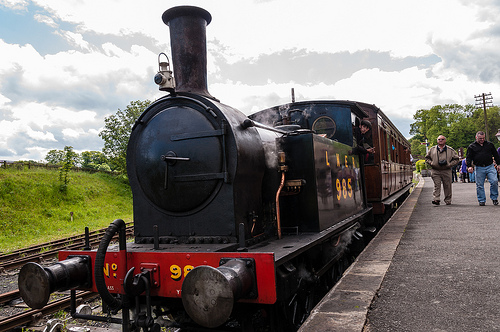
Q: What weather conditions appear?
A: It is cloudy.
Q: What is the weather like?
A: It is cloudy.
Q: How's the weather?
A: It is cloudy.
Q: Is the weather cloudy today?
A: Yes, it is cloudy.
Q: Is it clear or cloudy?
A: It is cloudy.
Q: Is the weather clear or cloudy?
A: It is cloudy.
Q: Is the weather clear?
A: No, it is cloudy.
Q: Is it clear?
A: No, it is cloudy.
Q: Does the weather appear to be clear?
A: No, it is cloudy.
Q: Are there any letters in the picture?
A: Yes, there are letters.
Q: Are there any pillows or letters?
A: Yes, there are letters.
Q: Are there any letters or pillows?
A: Yes, there are letters.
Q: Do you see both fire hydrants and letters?
A: No, there are letters but no fire hydrants.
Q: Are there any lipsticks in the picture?
A: No, there are no lipsticks.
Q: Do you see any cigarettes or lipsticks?
A: No, there are no lipsticks or cigarettes.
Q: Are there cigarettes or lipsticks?
A: No, there are no lipsticks or cigarettes.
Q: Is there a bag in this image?
A: No, there are no bags.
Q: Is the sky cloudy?
A: Yes, the sky is cloudy.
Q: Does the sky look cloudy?
A: Yes, the sky is cloudy.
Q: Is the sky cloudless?
A: No, the sky is cloudy.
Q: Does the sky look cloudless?
A: No, the sky is cloudy.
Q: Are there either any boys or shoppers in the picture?
A: No, there are no boys or shoppers.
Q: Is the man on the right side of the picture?
A: Yes, the man is on the right of the image.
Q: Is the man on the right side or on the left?
A: The man is on the right of the image.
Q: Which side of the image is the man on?
A: The man is on the right of the image.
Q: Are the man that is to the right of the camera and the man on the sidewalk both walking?
A: Yes, both the man and the man are walking.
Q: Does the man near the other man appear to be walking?
A: Yes, the man is walking.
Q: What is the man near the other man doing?
A: The man is walking.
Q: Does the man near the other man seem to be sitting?
A: No, the man is walking.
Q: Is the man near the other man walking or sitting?
A: The man is walking.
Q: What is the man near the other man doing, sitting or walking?
A: The man is walking.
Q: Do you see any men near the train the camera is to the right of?
A: Yes, there is a man near the train.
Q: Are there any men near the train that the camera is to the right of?
A: Yes, there is a man near the train.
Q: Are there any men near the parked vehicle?
A: Yes, there is a man near the train.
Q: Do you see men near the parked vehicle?
A: Yes, there is a man near the train.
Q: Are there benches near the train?
A: No, there is a man near the train.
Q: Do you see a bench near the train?
A: No, there is a man near the train.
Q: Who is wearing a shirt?
A: The man is wearing a shirt.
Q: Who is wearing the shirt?
A: The man is wearing a shirt.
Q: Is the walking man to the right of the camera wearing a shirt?
A: Yes, the man is wearing a shirt.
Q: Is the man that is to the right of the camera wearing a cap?
A: No, the man is wearing a shirt.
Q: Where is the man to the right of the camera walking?
A: The man is walking on the sidewalk.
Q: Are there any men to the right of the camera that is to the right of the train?
A: Yes, there is a man to the right of the camera.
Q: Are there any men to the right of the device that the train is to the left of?
A: Yes, there is a man to the right of the camera.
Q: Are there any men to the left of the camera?
A: No, the man is to the right of the camera.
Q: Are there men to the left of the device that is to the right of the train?
A: No, the man is to the right of the camera.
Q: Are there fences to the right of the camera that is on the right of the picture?
A: No, there is a man to the right of the camera.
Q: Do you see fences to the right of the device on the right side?
A: No, there is a man to the right of the camera.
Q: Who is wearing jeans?
A: The man is wearing jeans.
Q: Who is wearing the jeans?
A: The man is wearing jeans.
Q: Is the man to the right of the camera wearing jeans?
A: Yes, the man is wearing jeans.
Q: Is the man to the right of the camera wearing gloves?
A: No, the man is wearing jeans.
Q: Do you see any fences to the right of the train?
A: No, there is a man to the right of the train.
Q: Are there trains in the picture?
A: Yes, there is a train.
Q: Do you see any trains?
A: Yes, there is a train.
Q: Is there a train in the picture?
A: Yes, there is a train.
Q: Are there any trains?
A: Yes, there is a train.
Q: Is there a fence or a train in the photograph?
A: Yes, there is a train.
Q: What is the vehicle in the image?
A: The vehicle is a train.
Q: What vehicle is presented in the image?
A: The vehicle is a train.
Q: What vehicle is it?
A: The vehicle is a train.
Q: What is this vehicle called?
A: This is a train.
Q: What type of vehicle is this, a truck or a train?
A: This is a train.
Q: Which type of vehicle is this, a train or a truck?
A: This is a train.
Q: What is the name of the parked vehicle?
A: The vehicle is a train.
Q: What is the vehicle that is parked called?
A: The vehicle is a train.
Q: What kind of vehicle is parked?
A: The vehicle is a train.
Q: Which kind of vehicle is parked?
A: The vehicle is a train.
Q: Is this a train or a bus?
A: This is a train.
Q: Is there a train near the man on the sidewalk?
A: Yes, there is a train near the man.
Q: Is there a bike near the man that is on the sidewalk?
A: No, there is a train near the man.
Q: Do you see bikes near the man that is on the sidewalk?
A: No, there is a train near the man.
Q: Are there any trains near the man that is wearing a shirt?
A: Yes, there is a train near the man.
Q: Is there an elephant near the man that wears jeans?
A: No, there is a train near the man.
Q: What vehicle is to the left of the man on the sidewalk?
A: The vehicle is a train.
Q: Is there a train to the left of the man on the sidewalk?
A: Yes, there is a train to the left of the man.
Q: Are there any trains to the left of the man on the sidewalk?
A: Yes, there is a train to the left of the man.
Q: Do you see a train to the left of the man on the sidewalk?
A: Yes, there is a train to the left of the man.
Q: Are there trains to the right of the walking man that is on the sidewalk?
A: No, the train is to the left of the man.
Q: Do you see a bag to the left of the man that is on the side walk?
A: No, there is a train to the left of the man.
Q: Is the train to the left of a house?
A: No, the train is to the left of the man.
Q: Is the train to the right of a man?
A: No, the train is to the left of a man.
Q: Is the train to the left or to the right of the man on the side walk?
A: The train is to the left of the man.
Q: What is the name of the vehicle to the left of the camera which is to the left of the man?
A: The vehicle is a train.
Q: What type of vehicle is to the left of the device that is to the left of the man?
A: The vehicle is a train.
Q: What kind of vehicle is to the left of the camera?
A: The vehicle is a train.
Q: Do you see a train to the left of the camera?
A: Yes, there is a train to the left of the camera.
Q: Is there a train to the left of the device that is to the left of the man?
A: Yes, there is a train to the left of the camera.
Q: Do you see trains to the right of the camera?
A: No, the train is to the left of the camera.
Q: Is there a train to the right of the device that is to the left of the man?
A: No, the train is to the left of the camera.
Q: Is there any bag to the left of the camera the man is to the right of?
A: No, there is a train to the left of the camera.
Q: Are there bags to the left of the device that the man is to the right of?
A: No, there is a train to the left of the camera.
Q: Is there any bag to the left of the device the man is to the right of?
A: No, there is a train to the left of the camera.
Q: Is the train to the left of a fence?
A: No, the train is to the left of the camera.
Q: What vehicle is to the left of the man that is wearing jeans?
A: The vehicle is a train.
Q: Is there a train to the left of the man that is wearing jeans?
A: Yes, there is a train to the left of the man.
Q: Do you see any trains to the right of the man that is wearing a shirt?
A: No, the train is to the left of the man.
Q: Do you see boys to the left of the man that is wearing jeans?
A: No, there is a train to the left of the man.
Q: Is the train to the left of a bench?
A: No, the train is to the left of the man.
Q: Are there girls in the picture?
A: No, there are no girls.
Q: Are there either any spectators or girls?
A: No, there are no girls or spectators.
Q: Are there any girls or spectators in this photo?
A: No, there are no girls or spectators.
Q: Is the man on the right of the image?
A: Yes, the man is on the right of the image.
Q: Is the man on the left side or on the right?
A: The man is on the right of the image.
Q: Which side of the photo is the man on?
A: The man is on the right of the image.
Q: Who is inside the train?
A: The man is inside the train.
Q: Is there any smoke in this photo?
A: Yes, there is smoke.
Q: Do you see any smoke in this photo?
A: Yes, there is smoke.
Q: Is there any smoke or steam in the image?
A: Yes, there is smoke.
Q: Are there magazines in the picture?
A: No, there are no magazines.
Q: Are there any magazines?
A: No, there are no magazines.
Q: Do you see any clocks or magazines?
A: No, there are no magazines or clocks.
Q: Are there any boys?
A: No, there are no boys.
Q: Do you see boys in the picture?
A: No, there are no boys.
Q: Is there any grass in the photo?
A: Yes, there is grass.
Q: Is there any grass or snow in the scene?
A: Yes, there is grass.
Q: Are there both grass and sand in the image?
A: No, there is grass but no sand.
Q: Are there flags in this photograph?
A: No, there are no flags.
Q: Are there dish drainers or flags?
A: No, there are no flags or dish drainers.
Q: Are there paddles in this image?
A: No, there are no paddles.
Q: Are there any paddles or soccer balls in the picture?
A: No, there are no paddles or soccer balls.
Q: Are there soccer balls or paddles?
A: No, there are no paddles or soccer balls.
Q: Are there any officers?
A: No, there are no officers.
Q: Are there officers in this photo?
A: No, there are no officers.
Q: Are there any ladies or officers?
A: No, there are no officers or ladies.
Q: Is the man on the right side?
A: Yes, the man is on the right of the image.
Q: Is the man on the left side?
A: No, the man is on the right of the image.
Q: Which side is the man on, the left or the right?
A: The man is on the right of the image.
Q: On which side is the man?
A: The man is on the right of the image.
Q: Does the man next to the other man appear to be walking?
A: Yes, the man is walking.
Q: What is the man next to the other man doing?
A: The man is walking.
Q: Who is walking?
A: The man is walking.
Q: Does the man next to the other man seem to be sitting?
A: No, the man is walking.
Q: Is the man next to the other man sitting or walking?
A: The man is walking.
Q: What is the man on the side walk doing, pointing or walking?
A: The man is walking.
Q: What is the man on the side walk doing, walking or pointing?
A: The man is walking.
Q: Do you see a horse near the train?
A: No, there is a man near the train.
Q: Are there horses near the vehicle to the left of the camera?
A: No, there is a man near the train.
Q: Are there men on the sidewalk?
A: Yes, there is a man on the sidewalk.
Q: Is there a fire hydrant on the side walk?
A: No, there is a man on the side walk.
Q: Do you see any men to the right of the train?
A: Yes, there is a man to the right of the train.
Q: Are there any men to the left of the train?
A: No, the man is to the right of the train.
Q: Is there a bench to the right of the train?
A: No, there is a man to the right of the train.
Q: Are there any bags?
A: No, there are no bags.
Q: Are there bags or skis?
A: No, there are no bags or skis.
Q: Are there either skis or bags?
A: No, there are no bags or skis.